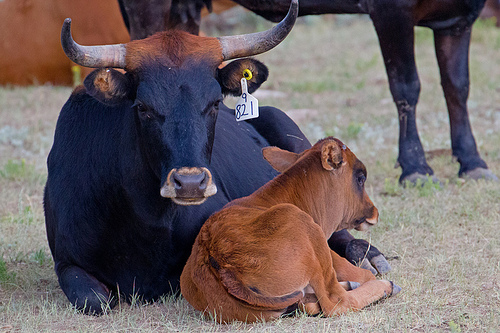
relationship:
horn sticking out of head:
[217, 2, 301, 59] [69, 1, 298, 203]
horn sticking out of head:
[63, 19, 126, 68] [69, 1, 298, 203]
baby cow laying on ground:
[179, 136, 402, 326] [0, 8, 498, 330]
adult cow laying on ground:
[41, 0, 388, 318] [0, 8, 498, 330]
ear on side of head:
[320, 139, 342, 174] [301, 137, 376, 229]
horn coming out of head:
[217, 0, 301, 62] [79, 42, 258, 207]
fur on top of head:
[121, 22, 249, 81] [48, 10, 348, 209]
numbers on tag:
[232, 99, 262, 122] [225, 59, 275, 126]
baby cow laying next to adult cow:
[179, 136, 402, 326] [41, 0, 388, 318]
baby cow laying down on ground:
[179, 136, 402, 326] [0, 8, 498, 330]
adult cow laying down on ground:
[41, 0, 388, 318] [0, 8, 498, 330]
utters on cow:
[171, 0, 216, 27] [118, 1, 498, 184]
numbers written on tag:
[232, 100, 256, 117] [232, 71, 259, 121]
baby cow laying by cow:
[179, 136, 402, 326] [39, 2, 391, 277]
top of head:
[124, 29, 224, 75] [69, 1, 298, 203]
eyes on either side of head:
[128, 92, 230, 124] [120, 30, 234, 206]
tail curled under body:
[206, 255, 306, 311] [178, 132, 393, 314]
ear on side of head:
[305, 131, 358, 169] [263, 133, 381, 237]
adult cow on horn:
[41, 0, 388, 318] [60, 16, 126, 68]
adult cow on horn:
[41, 0, 388, 318] [217, 2, 301, 59]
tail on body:
[206, 255, 315, 321] [176, 130, 395, 331]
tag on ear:
[228, 90, 262, 126] [207, 52, 301, 99]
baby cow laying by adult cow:
[232, 158, 362, 278] [39, 2, 393, 311]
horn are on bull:
[217, 0, 301, 62] [38, 5, 411, 309]